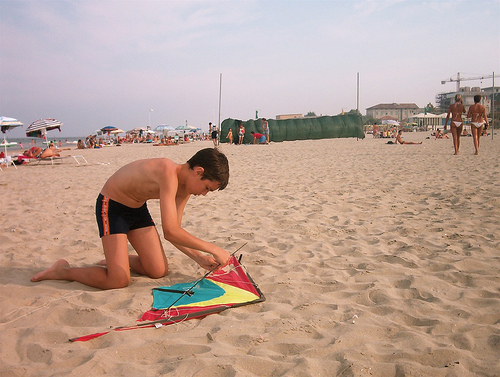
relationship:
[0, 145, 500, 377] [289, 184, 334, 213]
beach has footprints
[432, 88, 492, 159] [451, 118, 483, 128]
ladies wearing bikinis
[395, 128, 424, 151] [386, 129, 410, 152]
man sun bathing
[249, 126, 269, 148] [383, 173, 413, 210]
man bending on ground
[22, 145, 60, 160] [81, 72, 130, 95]
lady basking in sun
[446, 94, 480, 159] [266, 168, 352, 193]
women walking on beach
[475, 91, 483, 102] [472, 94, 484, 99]
hair short brown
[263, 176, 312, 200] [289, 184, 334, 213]
sand has footprints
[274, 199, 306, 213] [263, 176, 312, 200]
divets in sand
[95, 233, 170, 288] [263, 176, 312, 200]
boy in sand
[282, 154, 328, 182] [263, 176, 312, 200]
ground has sand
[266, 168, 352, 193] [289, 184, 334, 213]
beach has footprints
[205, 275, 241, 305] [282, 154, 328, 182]
kite on ground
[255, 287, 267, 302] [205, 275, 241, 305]
top of kite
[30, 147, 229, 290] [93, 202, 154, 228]
boy has shorts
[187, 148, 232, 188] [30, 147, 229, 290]
head on boy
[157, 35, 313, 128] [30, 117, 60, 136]
background has unbrella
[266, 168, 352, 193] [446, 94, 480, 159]
beach has women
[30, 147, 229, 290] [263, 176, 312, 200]
boy kneeling on sand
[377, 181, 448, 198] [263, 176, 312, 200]
footsteps in sand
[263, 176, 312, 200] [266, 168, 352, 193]
sand on beach